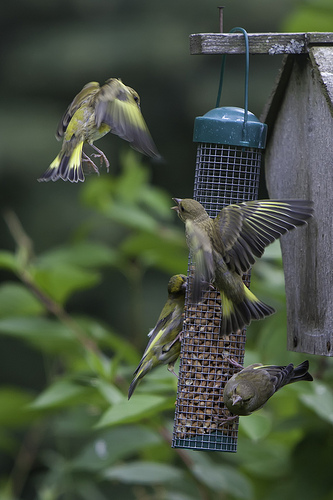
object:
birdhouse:
[262, 28, 332, 183]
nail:
[217, 5, 225, 33]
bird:
[169, 190, 300, 298]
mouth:
[166, 191, 180, 211]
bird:
[221, 361, 315, 421]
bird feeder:
[171, 108, 265, 452]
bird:
[127, 268, 188, 399]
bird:
[38, 76, 157, 188]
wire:
[166, 141, 243, 447]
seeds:
[174, 276, 243, 435]